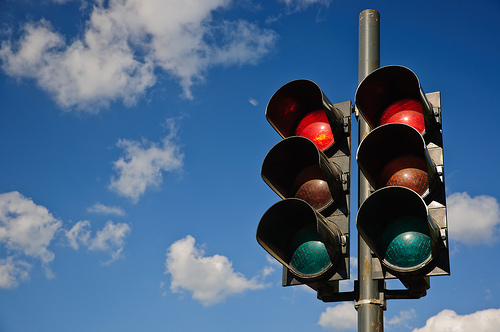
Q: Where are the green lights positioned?
A: At the bottom.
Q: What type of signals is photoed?
A: Double three way signals.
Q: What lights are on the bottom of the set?
A: Green lights.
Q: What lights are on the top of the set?
A: Red lights.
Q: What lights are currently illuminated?
A: Red lights.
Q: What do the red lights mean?
A: Stop.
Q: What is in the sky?
A: Clouds.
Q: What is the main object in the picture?
A: Traffic light.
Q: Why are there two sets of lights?
A: There are two lanes of traffic.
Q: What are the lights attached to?
A: A pole.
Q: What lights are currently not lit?
A: Green and yellow.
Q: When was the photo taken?
A: During the daytime.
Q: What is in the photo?
A: Lights.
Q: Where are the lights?
A: On the pole.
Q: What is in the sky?
A: Clouds.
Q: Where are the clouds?
A: In the sky.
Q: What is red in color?
A: The top light.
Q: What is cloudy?
A: The sky.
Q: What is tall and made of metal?
A: Pole.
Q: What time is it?
A: Afternoon.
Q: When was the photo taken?
A: During the daytime.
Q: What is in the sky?
A: Clouds.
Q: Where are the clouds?
A: In the sky.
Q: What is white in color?
A: The clouds.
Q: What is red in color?
A: One of the lights.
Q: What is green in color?
A: Bottom light.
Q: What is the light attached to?
A: A pole.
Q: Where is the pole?
A: Next to the light.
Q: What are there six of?
A: Lights.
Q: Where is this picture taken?
A: An intersection.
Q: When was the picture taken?
A: During daytime.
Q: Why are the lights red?
A: To stop traffic.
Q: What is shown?
A: Traffic lights.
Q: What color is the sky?
A: Blue.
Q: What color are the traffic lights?
A: Red , orange and green.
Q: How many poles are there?
A: One.